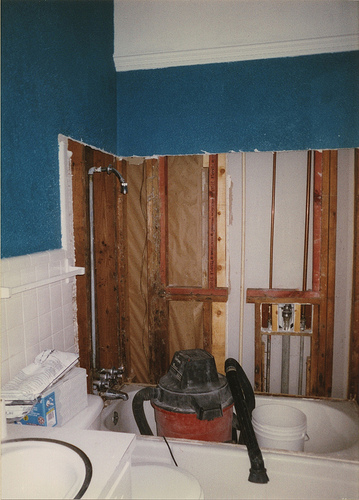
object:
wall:
[280, 117, 281, 139]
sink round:
[0, 427, 85, 497]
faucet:
[91, 375, 129, 403]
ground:
[313, 89, 326, 104]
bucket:
[248, 399, 309, 460]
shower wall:
[56, 129, 358, 403]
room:
[3, 1, 357, 497]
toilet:
[43, 390, 204, 497]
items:
[0, 340, 103, 452]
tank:
[60, 393, 106, 433]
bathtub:
[96, 377, 355, 498]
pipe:
[86, 161, 102, 373]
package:
[0, 349, 88, 427]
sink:
[0, 438, 92, 498]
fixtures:
[91, 361, 128, 402]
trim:
[4, 429, 93, 498]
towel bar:
[0, 261, 87, 304]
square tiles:
[4, 249, 82, 399]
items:
[131, 350, 269, 485]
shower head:
[96, 163, 128, 198]